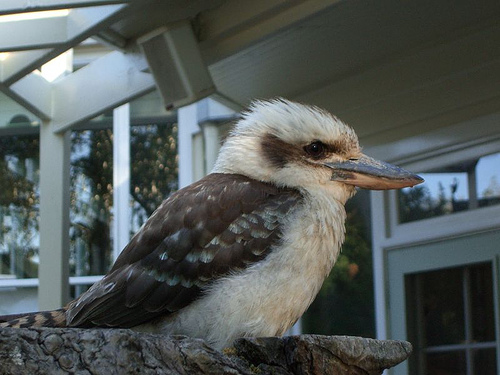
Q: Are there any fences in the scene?
A: No, there are no fences.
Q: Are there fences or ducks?
A: No, there are no fences or ducks.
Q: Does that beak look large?
A: Yes, the beak is large.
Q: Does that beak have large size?
A: Yes, the beak is large.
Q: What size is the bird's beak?
A: The beak is large.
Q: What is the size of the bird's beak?
A: The beak is large.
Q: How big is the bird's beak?
A: The beak is large.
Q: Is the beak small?
A: No, the beak is large.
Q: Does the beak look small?
A: No, the beak is large.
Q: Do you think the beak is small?
A: No, the beak is large.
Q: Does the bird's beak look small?
A: No, the beak is large.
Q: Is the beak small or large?
A: The beak is large.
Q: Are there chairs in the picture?
A: No, there are no chairs.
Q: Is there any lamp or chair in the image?
A: No, there are no chairs or lamps.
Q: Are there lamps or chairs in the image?
A: No, there are no chairs or lamps.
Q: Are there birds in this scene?
A: Yes, there is a bird.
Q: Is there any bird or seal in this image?
A: Yes, there is a bird.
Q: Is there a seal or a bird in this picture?
A: Yes, there is a bird.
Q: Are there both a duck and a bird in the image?
A: No, there is a bird but no ducks.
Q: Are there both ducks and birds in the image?
A: No, there is a bird but no ducks.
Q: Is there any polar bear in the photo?
A: No, there are no polar bears.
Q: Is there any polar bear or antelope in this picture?
A: No, there are no polar bears or antelopes.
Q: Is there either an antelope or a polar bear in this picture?
A: No, there are no polar bears or antelopes.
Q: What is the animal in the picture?
A: The animal is a bird.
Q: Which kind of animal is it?
A: The animal is a bird.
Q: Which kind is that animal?
A: That is a bird.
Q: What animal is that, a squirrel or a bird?
A: That is a bird.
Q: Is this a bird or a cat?
A: This is a bird.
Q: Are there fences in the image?
A: No, there are no fences.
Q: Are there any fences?
A: No, there are no fences.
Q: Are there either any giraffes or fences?
A: No, there are no fences or giraffes.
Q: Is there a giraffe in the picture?
A: No, there are no giraffes.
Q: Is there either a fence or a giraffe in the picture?
A: No, there are no giraffes or fences.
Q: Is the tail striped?
A: Yes, the tail is striped.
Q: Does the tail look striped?
A: Yes, the tail is striped.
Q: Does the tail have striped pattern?
A: Yes, the tail is striped.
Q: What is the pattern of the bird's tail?
A: The tail is striped.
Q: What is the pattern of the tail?
A: The tail is striped.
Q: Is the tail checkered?
A: No, the tail is striped.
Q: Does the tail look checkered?
A: No, the tail is striped.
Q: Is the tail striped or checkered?
A: The tail is striped.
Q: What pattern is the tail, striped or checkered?
A: The tail is striped.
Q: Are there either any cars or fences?
A: No, there are no fences or cars.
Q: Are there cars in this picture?
A: No, there are no cars.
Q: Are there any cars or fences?
A: No, there are no cars or fences.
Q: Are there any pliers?
A: No, there are no pliers.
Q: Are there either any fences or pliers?
A: No, there are no pliers or fences.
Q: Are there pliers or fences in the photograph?
A: No, there are no pliers or fences.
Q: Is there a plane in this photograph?
A: No, there are no airplanes.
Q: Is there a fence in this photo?
A: No, there are no fences.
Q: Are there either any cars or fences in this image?
A: No, there are no fences or cars.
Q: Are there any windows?
A: Yes, there is a window.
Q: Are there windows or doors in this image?
A: Yes, there is a window.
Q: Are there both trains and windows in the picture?
A: No, there is a window but no trains.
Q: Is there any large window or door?
A: Yes, there is a large window.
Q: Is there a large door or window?
A: Yes, there is a large window.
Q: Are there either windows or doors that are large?
A: Yes, the window is large.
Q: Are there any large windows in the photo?
A: Yes, there is a large window.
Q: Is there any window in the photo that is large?
A: Yes, there is a window that is large.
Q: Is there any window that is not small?
A: Yes, there is a large window.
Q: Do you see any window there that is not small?
A: Yes, there is a large window.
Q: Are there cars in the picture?
A: No, there are no cars.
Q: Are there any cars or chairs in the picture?
A: No, there are no cars or chairs.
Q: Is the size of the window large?
A: Yes, the window is large.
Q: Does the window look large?
A: Yes, the window is large.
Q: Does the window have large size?
A: Yes, the window is large.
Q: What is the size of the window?
A: The window is large.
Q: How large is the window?
A: The window is large.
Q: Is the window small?
A: No, the window is large.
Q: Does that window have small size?
A: No, the window is large.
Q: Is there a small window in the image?
A: No, there is a window but it is large.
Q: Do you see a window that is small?
A: No, there is a window but it is large.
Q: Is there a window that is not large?
A: No, there is a window but it is large.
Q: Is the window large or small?
A: The window is large.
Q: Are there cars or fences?
A: No, there are no fences or cars.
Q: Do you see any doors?
A: Yes, there is a door.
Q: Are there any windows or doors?
A: Yes, there is a door.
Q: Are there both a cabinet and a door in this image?
A: No, there is a door but no cabinets.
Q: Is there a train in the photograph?
A: No, there are no trains.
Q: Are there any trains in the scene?
A: No, there are no trains.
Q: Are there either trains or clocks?
A: No, there are no trains or clocks.